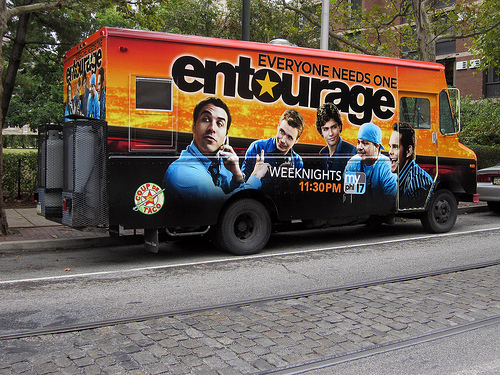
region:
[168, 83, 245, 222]
A movie star on a lorry wall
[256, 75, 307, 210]
A movie star on a lorry wall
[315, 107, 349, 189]
A movie star on a lorry wall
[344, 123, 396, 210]
A movie star on a lorry wall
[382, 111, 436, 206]
A movie star on a lorry wall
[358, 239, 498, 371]
A grey tile road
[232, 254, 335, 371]
A grey tile road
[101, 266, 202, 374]
A grey tile road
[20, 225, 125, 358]
A grey tile road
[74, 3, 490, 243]
A big yellow truck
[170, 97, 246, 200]
this is a person's picture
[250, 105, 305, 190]
this is a person's picture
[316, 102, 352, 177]
this is a person's picture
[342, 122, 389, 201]
this is a person's picture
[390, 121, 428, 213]
this is a person's picture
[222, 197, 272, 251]
this is a wheel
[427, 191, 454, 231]
this is a wheel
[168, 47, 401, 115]
this is a sentence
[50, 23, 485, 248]
this is a truck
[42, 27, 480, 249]
this is a black and orange truck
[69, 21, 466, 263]
this is a lorry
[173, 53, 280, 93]
this is a writing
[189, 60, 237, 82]
the writing is in black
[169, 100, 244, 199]
this is a man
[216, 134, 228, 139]
the man is light skinned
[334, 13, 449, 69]
this is a tree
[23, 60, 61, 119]
the leaves are green in color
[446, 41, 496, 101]
this is a building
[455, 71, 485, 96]
this is the wall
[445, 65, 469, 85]
the wall is brown in color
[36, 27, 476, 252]
A colorful truck parked on the road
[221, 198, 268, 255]
The rear wheel of a truck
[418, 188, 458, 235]
The front wheel of a truck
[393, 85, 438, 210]
The passenger side door of a truck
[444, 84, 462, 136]
The side mirror of an orange truck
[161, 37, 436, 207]
Advertisement on the side of a truck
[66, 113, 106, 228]
Gray tank in a wire enclosure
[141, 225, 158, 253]
Mudflap on the underside of a truck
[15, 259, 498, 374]
Bricks laid in the center of a road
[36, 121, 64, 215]
A tank in a wire enclosure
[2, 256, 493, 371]
strip of cobblestone between two metal rails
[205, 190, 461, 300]
black wheels by white line on street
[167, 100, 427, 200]
men looking at each other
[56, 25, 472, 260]
truck with advertisement on side and back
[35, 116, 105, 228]
two white cylinders in metal cases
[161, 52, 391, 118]
yellow star in letter of word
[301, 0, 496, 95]
pole and trees in front of building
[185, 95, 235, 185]
man holding cell phone to his ear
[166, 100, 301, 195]
man with face turned while holding hand up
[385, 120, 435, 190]
man in striped shirt laughing